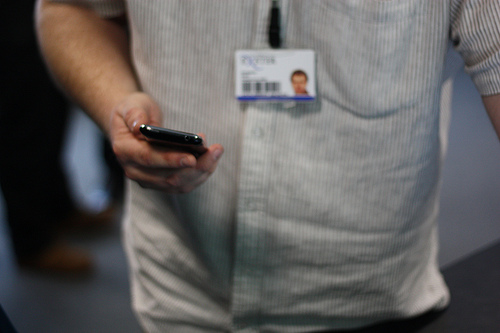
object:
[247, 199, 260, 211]
button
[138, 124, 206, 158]
cellphone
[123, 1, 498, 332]
shirt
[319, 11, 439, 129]
pocket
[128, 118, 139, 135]
reflection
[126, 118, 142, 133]
thumbnail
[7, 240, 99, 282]
brown shoe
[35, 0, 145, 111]
arm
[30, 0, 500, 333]
worker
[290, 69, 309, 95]
face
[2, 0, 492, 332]
photo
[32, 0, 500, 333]
guy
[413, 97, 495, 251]
wall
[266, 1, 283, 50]
lanyard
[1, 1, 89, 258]
slacks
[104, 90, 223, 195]
hand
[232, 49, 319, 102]
id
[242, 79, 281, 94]
barcode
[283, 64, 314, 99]
picture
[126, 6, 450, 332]
edge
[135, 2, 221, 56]
part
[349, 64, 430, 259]
part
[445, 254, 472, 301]
part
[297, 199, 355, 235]
part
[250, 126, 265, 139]
button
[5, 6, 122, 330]
background